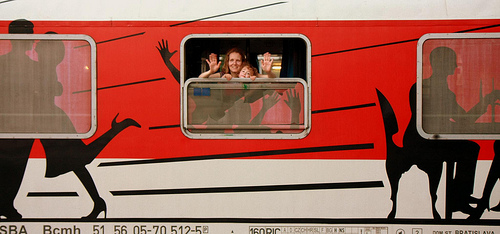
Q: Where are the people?
A: Behind a window.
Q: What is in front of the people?
A: A window.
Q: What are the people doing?
A: Waving.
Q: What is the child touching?
A: The window sill.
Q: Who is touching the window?
A: The little child.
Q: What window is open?
A: The window the people are waving out of.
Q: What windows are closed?
A: The windows around the one with the people.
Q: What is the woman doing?
A: Waving.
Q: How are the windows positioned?
A: In a row.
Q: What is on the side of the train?
A: Silhouettes of people.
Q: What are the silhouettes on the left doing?
A: Dancing.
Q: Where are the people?
A: In the train window.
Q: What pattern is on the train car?
A: Red and white with black stripes and silhouettes.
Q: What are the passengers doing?
A: Waving from the train window.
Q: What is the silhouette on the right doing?
A: Sitting in a chair.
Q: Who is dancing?
A: The man and woman in the silhouette.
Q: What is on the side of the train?
A: Artwork.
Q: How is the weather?
A: Sunny and clear.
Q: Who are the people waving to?
A: The camera person.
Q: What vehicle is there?
A: Bus.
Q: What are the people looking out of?
A: Window.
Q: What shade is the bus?
A: Red, black and white.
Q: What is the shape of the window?
A: Rectangular.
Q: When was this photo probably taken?
A: Daytime.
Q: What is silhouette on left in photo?
A: Man and woman.